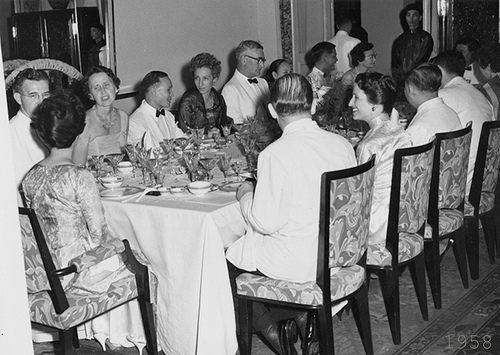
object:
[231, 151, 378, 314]
chair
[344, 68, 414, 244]
woman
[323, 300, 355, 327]
stilettos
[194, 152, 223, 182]
glass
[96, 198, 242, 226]
table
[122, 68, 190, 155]
man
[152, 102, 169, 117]
bow tie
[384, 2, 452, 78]
attendant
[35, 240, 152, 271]
armest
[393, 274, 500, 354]
rug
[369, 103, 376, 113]
earring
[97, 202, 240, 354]
tablecloth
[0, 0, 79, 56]
mirror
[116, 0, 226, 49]
wall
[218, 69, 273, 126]
suit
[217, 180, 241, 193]
plate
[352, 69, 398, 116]
hair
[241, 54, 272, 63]
glasses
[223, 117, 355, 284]
jacket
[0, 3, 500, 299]
people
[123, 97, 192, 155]
shirt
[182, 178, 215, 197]
bowl